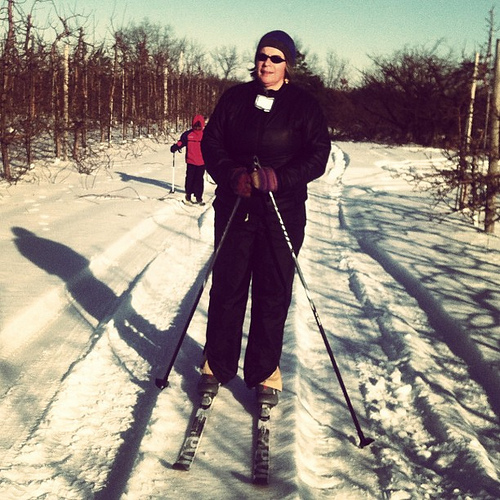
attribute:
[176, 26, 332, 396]
woman — skiing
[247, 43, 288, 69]
glasses — pair, dark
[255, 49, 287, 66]
glasses — black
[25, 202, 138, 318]
snow — skis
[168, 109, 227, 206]
skier — wearing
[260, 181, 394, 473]
ski pole — white and black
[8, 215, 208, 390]
shadow — covered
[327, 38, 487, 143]
trees — clump, leaveless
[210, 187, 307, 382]
pants — black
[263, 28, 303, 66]
hat — blue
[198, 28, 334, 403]
skier — relaxed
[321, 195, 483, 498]
tracks — tire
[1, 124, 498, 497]
ground — snow, snow covered